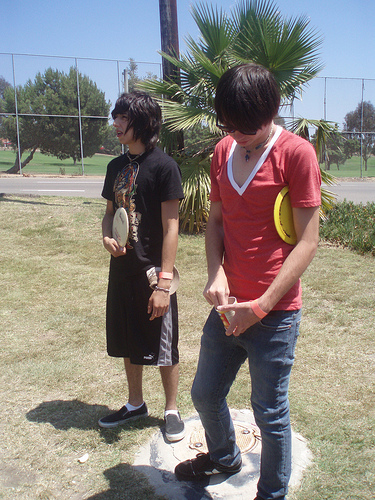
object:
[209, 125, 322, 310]
shirt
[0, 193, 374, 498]
ground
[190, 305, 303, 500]
jeans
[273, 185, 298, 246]
frisbee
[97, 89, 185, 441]
boy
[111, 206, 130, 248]
frisbee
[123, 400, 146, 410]
socks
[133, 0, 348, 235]
tree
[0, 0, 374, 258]
background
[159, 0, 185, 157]
pole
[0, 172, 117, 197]
road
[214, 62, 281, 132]
hair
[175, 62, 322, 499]
boys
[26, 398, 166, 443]
shadows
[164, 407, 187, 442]
sneakers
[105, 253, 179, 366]
shorts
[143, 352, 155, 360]
logo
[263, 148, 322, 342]
arm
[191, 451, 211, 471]
laces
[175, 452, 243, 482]
shoe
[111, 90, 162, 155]
hair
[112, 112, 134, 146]
face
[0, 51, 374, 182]
fence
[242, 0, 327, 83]
frond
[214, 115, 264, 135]
sunglasses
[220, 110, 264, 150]
face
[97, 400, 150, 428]
shoes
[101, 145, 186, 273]
shirt